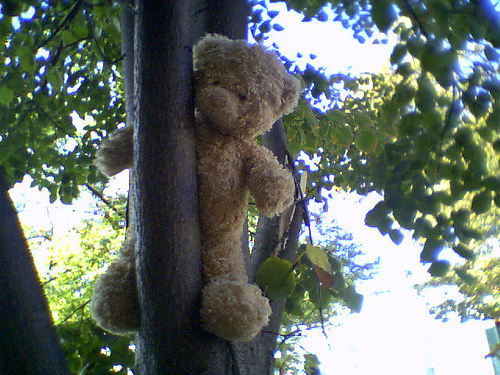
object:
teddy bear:
[86, 29, 317, 350]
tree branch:
[128, 3, 235, 373]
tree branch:
[241, 100, 319, 371]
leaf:
[253, 255, 301, 302]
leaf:
[357, 130, 377, 152]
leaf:
[428, 260, 450, 279]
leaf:
[308, 265, 336, 292]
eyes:
[204, 74, 253, 106]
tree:
[1, 7, 494, 373]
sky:
[255, 12, 390, 78]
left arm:
[249, 139, 296, 217]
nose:
[201, 91, 228, 109]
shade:
[13, 3, 491, 374]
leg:
[193, 223, 272, 344]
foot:
[201, 283, 273, 339]